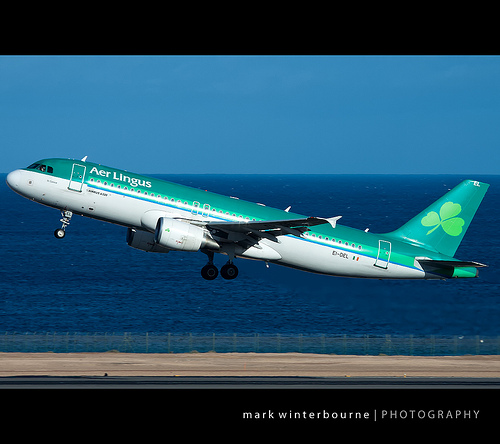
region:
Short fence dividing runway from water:
[4, 331, 499, 356]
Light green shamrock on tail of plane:
[418, 199, 465, 237]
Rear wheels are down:
[199, 252, 241, 283]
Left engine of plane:
[157, 215, 204, 252]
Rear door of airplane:
[373, 238, 392, 270]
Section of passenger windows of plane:
[83, 175, 195, 207]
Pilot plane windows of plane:
[30, 161, 56, 174]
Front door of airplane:
[67, 162, 87, 194]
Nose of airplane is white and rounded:
[5, 166, 26, 191]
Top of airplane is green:
[174, 181, 259, 210]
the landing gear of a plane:
[53, 215, 71, 242]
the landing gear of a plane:
[201, 252, 219, 284]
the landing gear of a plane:
[220, 250, 239, 283]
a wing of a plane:
[221, 206, 343, 243]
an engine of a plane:
[123, 225, 153, 253]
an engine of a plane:
[151, 217, 206, 255]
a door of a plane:
[66, 158, 87, 195]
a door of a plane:
[373, 235, 394, 271]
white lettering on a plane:
[88, 163, 153, 190]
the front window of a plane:
[26, 160, 58, 177]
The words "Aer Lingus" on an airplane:
[87, 158, 158, 197]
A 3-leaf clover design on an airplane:
[410, 189, 475, 242]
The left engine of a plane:
[155, 215, 220, 263]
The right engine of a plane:
[120, 220, 169, 264]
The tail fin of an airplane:
[401, 169, 496, 271]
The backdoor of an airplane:
[370, 228, 397, 283]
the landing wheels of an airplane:
[191, 262, 252, 283]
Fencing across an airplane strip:
[0, 329, 499, 349]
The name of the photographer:
[232, 393, 497, 436]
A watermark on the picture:
[232, 398, 499, 433]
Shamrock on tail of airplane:
[373, 158, 490, 294]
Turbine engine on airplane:
[147, 200, 333, 298]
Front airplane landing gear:
[41, 199, 89, 250]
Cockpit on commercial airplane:
[3, 145, 154, 245]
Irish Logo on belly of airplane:
[319, 230, 396, 285]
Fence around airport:
[23, 266, 198, 353]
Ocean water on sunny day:
[19, 248, 120, 322]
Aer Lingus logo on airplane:
[60, 150, 171, 227]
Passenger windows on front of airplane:
[84, 173, 276, 230]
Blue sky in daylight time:
[266, 62, 457, 158]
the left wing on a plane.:
[197, 184, 347, 266]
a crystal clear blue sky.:
[0, 54, 497, 175]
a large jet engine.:
[143, 208, 220, 267]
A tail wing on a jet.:
[381, 132, 496, 262]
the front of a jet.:
[8, 147, 61, 202]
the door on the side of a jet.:
[60, 166, 95, 211]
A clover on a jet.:
[400, 197, 477, 244]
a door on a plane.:
[65, 142, 91, 207]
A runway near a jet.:
[3, 342, 498, 384]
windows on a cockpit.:
[29, 139, 74, 173]